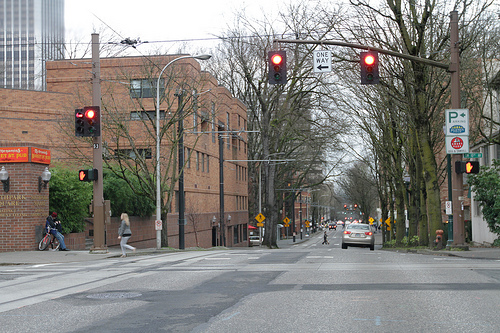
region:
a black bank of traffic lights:
[263, 47, 293, 89]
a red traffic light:
[267, 47, 285, 67]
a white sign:
[307, 45, 334, 75]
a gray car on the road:
[337, 217, 379, 249]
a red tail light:
[339, 226, 354, 238]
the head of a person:
[117, 208, 133, 222]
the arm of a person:
[116, 220, 126, 236]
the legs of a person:
[118, 233, 136, 255]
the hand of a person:
[115, 232, 122, 240]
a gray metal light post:
[153, 52, 195, 253]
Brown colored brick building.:
[125, 56, 268, 233]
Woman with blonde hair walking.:
[109, 204, 146, 275]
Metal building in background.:
[10, 5, 43, 85]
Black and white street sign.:
[309, 37, 338, 87]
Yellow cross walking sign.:
[249, 207, 272, 252]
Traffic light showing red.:
[258, 45, 294, 103]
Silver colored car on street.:
[335, 215, 403, 266]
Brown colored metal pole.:
[443, 40, 472, 253]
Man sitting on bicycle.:
[33, 208, 75, 261]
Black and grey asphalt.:
[220, 266, 385, 330]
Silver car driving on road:
[338, 219, 378, 253]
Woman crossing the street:
[113, 210, 138, 260]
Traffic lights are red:
[259, 46, 384, 88]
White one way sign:
[311, 48, 333, 73]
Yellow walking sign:
[253, 210, 266, 228]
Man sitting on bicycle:
[33, 205, 71, 256]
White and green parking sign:
[445, 105, 470, 138]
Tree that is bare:
[237, 49, 339, 247]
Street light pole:
[440, 10, 470, 250]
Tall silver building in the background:
[1, 0, 63, 92]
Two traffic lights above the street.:
[256, 27, 392, 92]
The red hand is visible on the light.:
[75, 160, 95, 180]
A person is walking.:
[100, 206, 150, 261]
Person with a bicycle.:
[26, 201, 73, 254]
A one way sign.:
[310, 45, 333, 78]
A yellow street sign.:
[242, 198, 272, 254]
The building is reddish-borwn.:
[43, 40, 256, 247]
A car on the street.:
[335, 208, 377, 253]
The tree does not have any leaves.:
[325, 5, 496, 252]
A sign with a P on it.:
[445, 109, 469, 137]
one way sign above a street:
[314, 45, 331, 70]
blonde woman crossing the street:
[113, 207, 140, 262]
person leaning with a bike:
[37, 206, 71, 253]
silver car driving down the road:
[338, 221, 377, 253]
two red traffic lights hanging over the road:
[261, 45, 384, 89]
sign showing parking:
[443, 105, 473, 135]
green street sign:
[462, 147, 485, 161]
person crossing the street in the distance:
[320, 227, 331, 249]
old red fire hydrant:
[431, 227, 444, 250]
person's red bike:
[32, 223, 62, 250]